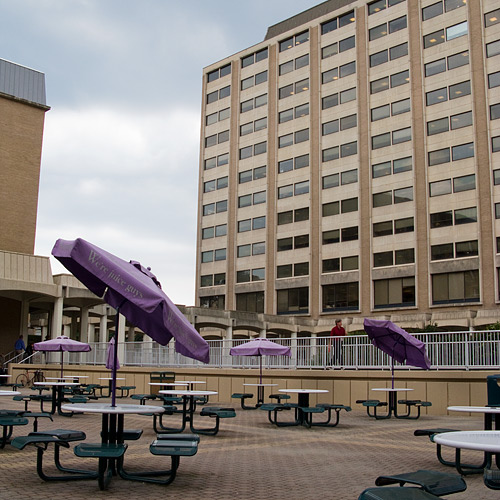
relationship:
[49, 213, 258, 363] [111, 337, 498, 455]
umbrella on patio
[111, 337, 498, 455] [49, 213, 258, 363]
patio with umbrella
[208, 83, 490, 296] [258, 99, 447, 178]
building has windows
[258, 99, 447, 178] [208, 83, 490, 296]
windows on building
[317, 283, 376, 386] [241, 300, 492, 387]
man on walkway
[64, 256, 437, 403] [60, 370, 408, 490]
umbrellas at tables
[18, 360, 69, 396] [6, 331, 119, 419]
bike near stairs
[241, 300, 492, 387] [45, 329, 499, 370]
walkway has fencing